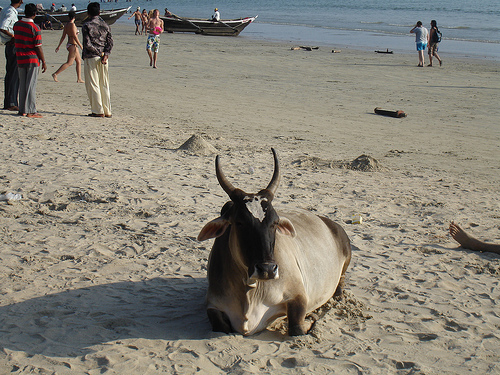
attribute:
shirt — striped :
[11, 19, 62, 76]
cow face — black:
[218, 196, 284, 280]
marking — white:
[242, 192, 265, 220]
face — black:
[233, 192, 279, 281]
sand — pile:
[177, 133, 214, 152]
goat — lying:
[192, 142, 361, 345]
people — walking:
[410, 17, 451, 72]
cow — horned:
[205, 150, 368, 350]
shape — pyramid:
[181, 124, 221, 160]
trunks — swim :
[139, 33, 166, 53]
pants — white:
[87, 56, 114, 114]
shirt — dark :
[81, 17, 113, 57]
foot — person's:
[47, 70, 57, 85]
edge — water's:
[301, 31, 371, 53]